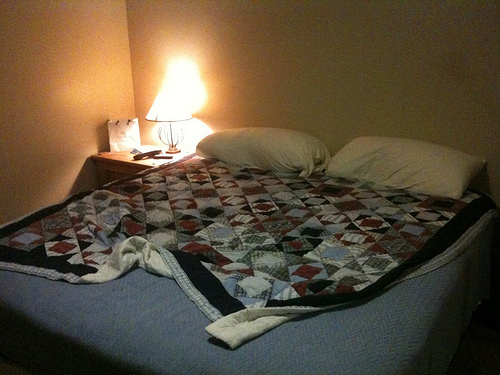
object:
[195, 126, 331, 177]
pillow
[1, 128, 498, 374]
bed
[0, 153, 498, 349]
bedspread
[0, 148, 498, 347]
blanket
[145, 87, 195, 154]
lamp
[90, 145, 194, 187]
table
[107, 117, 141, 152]
bag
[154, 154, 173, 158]
remotes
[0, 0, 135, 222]
wall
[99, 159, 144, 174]
drawer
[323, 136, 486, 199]
pillows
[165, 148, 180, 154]
base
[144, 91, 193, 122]
lamp shade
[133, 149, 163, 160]
remote